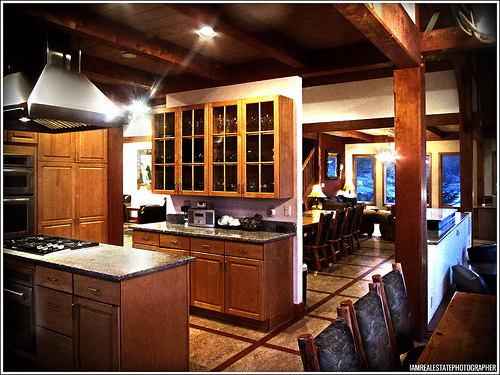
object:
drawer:
[31, 265, 77, 296]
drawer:
[188, 237, 225, 255]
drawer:
[158, 228, 192, 253]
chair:
[294, 304, 366, 373]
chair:
[370, 262, 430, 367]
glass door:
[207, 98, 242, 199]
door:
[241, 93, 277, 197]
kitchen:
[1, 34, 302, 372]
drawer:
[225, 240, 264, 259]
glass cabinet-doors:
[153, 106, 180, 195]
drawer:
[62, 267, 123, 307]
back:
[378, 270, 415, 342]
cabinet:
[257, 93, 293, 135]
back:
[295, 303, 363, 374]